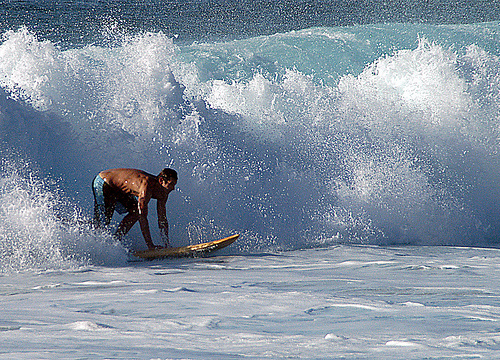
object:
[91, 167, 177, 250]
surfer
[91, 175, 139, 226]
shorts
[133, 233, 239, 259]
surfboard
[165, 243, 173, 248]
hand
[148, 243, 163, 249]
hand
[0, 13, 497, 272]
ocean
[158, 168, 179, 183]
hair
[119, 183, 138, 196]
ribs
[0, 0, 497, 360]
water